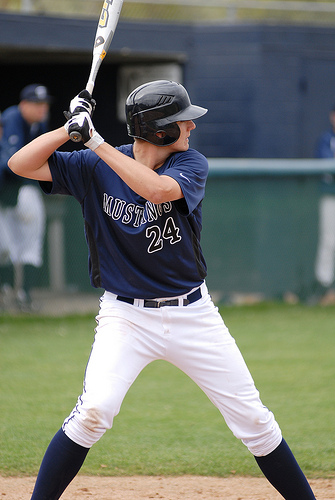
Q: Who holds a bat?
A: A baseball player.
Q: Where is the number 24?
A: On a shirt.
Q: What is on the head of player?
A: A helmet.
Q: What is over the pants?
A: A belt.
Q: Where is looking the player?
A: To the right.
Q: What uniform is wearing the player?
A: Color white and blue.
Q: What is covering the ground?
A: Green grass.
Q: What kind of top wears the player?
A: A tee shirt.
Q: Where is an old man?
A: Behind player.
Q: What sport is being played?
A: Baseball.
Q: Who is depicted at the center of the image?
A: The batter.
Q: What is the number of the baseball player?
A: 24.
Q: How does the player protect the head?
A: With the helmet.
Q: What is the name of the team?
A: Mustangs.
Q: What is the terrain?
A: Flat grass field.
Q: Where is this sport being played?
A: At a baseball diamond.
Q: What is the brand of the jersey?
A: Nike.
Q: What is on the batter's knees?
A: Dirt.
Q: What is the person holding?
A: Bat.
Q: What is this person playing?
A: Baseball.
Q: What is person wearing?
A: Jersey.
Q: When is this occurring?
A: During the day time.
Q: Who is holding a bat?
A: The man.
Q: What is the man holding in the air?
A: A bat.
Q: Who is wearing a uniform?
A: The man.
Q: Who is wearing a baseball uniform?
A: The man.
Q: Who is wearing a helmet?
A: The man.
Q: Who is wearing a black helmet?
A: The man.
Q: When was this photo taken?
A: Daytime.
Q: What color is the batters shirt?
A: Blue.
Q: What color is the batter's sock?
A: Blue.